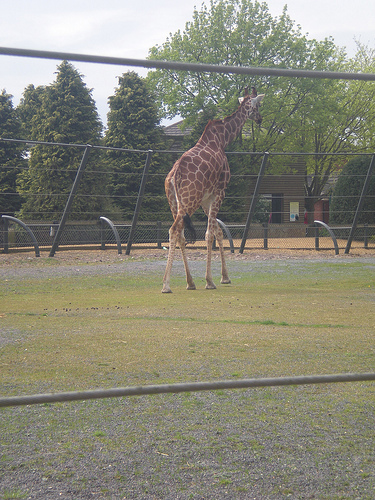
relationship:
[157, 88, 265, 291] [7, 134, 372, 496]
giraffe in enclosure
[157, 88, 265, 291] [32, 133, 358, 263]
giraffe in fence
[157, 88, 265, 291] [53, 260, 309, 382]
giraffe on ground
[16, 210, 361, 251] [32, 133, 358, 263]
structure on fence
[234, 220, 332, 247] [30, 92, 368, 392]
ground outside enclosure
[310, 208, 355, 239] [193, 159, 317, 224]
wall by building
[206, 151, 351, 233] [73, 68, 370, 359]
building behind enclosure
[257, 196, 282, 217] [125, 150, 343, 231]
window on building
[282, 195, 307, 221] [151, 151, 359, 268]
plaque on building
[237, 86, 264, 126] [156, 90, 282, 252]
head on giraffe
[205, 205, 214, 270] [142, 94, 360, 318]
leg on giraffe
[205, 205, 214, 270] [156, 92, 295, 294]
leg on giraffe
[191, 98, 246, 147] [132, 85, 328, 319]
neck on giraffe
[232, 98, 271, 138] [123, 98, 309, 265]
head on giraffe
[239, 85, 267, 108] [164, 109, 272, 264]
ear on giraffe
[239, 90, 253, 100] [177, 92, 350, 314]
ear on giraffe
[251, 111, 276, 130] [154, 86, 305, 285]
mouth on giraffe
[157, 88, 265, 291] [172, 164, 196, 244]
giraffe has tail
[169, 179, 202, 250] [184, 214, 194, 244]
tail has hair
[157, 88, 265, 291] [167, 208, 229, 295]
giraffe has legs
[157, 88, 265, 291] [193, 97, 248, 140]
giraffe has mane